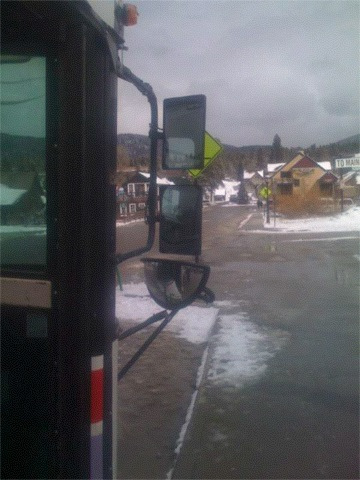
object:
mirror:
[140, 257, 210, 310]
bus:
[0, 0, 216, 479]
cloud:
[215, 74, 232, 93]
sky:
[339, 19, 357, 75]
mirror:
[159, 184, 203, 256]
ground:
[313, 214, 360, 259]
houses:
[244, 148, 360, 219]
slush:
[116, 275, 294, 390]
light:
[122, 3, 139, 26]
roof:
[50, 0, 126, 49]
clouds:
[299, 114, 320, 128]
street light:
[265, 177, 271, 223]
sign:
[260, 186, 272, 198]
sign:
[186, 129, 222, 178]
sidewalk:
[321, 210, 360, 231]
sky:
[200, 29, 233, 64]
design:
[90, 338, 118, 479]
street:
[300, 441, 356, 477]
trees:
[268, 133, 285, 164]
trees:
[306, 143, 332, 159]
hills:
[221, 133, 360, 162]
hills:
[115, 133, 165, 171]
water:
[291, 266, 325, 301]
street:
[285, 363, 325, 400]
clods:
[286, 17, 311, 38]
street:
[205, 216, 226, 245]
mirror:
[162, 93, 207, 170]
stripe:
[90, 353, 104, 479]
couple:
[257, 197, 263, 209]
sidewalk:
[238, 213, 266, 231]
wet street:
[222, 400, 280, 421]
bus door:
[0, 0, 91, 480]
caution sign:
[257, 187, 271, 223]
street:
[123, 451, 180, 476]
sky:
[140, 1, 183, 32]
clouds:
[183, 22, 208, 37]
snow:
[210, 331, 264, 375]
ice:
[151, 361, 171, 382]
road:
[114, 202, 358, 478]